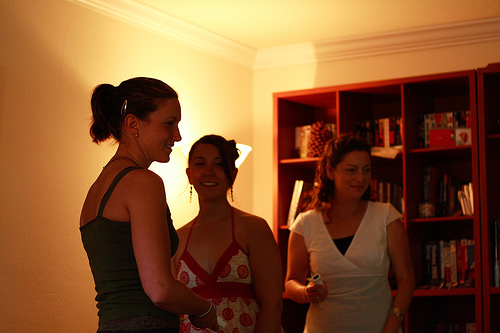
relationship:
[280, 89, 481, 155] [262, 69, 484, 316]
books on shelf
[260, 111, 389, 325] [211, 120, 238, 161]
woman has hair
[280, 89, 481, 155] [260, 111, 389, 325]
books behind woman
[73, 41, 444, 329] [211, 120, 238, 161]
women has hair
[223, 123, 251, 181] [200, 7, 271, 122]
light lighting wall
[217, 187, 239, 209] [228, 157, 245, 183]
earring on ear